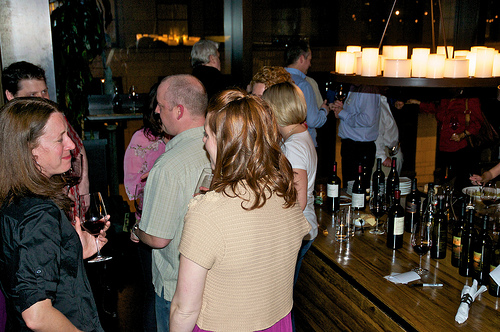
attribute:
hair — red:
[214, 97, 291, 217]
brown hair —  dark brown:
[0, 94, 80, 202]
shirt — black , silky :
[5, 191, 99, 329]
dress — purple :
[183, 297, 302, 329]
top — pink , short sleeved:
[175, 178, 315, 330]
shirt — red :
[422, 99, 464, 140]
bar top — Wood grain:
[314, 195, 499, 330]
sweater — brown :
[169, 162, 305, 329]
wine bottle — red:
[384, 185, 409, 252]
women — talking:
[2, 89, 313, 330]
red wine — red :
[80, 218, 105, 238]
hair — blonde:
[270, 87, 300, 120]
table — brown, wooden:
[289, 180, 499, 330]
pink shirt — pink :
[118, 125, 163, 211]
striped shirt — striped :
[177, 180, 309, 330]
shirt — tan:
[187, 193, 305, 328]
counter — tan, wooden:
[293, 180, 498, 325]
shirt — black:
[3, 177, 104, 329]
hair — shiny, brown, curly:
[188, 86, 310, 211]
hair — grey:
[165, 75, 207, 119]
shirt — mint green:
[131, 122, 214, 307]